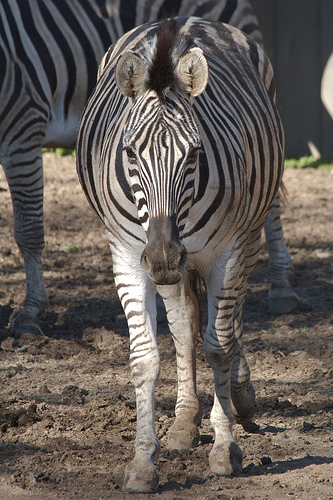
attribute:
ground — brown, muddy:
[21, 329, 113, 470]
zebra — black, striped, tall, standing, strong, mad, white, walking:
[98, 17, 272, 357]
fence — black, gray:
[280, 18, 331, 133]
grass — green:
[293, 148, 317, 174]